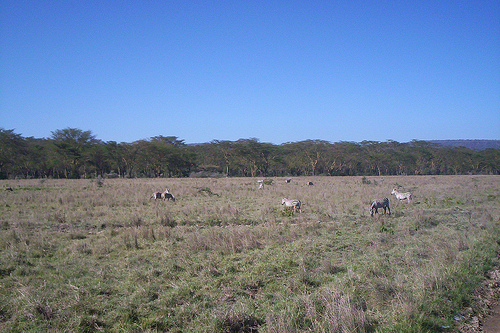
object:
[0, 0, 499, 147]
clouds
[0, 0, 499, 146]
sky